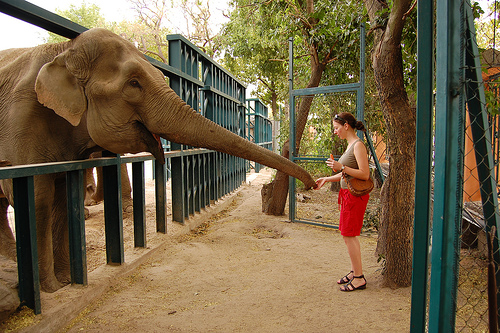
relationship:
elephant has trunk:
[15, 37, 321, 288] [129, 89, 313, 188]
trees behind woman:
[253, 1, 422, 292] [328, 121, 378, 294]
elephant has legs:
[80, 50, 154, 227] [80, 160, 141, 227]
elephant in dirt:
[15, 37, 321, 288] [80, 224, 144, 332]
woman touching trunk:
[328, 121, 378, 294] [129, 89, 313, 188]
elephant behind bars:
[15, 37, 321, 288] [172, 49, 247, 192]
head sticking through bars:
[51, 22, 172, 161] [172, 49, 247, 192]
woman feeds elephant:
[328, 121, 378, 294] [15, 37, 321, 288]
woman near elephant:
[328, 121, 378, 294] [15, 37, 321, 288]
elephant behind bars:
[15, 37, 321, 288] [165, 33, 248, 225]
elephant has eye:
[15, 37, 321, 288] [123, 71, 145, 99]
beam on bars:
[23, 5, 212, 87] [165, 33, 248, 225]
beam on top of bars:
[23, 5, 212, 87] [165, 33, 248, 225]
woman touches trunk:
[328, 121, 378, 294] [129, 89, 313, 188]